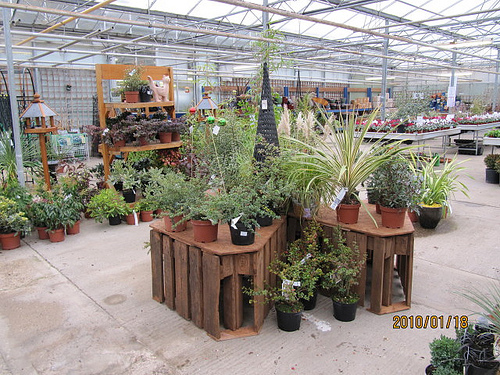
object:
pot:
[226, 213, 257, 245]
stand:
[149, 218, 321, 342]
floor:
[33, 152, 463, 359]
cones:
[244, 48, 298, 191]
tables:
[144, 160, 418, 341]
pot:
[414, 171, 454, 231]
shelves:
[94, 62, 207, 232]